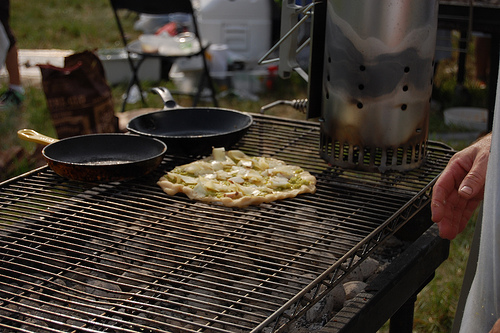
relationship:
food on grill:
[156, 144, 322, 208] [2, 92, 467, 324]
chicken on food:
[210, 143, 231, 159] [156, 144, 322, 208]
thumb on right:
[452, 153, 490, 202] [425, 127, 500, 246]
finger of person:
[426, 146, 469, 218] [428, 71, 499, 331]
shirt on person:
[459, 70, 495, 329] [428, 71, 499, 331]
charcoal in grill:
[14, 192, 388, 323] [2, 92, 467, 324]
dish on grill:
[16, 128, 168, 185] [2, 92, 467, 324]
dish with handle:
[16, 128, 168, 185] [13, 125, 60, 146]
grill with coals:
[2, 92, 467, 324] [8, 195, 400, 332]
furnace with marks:
[296, 2, 440, 171] [320, 94, 442, 158]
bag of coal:
[26, 46, 127, 140] [4, 211, 377, 331]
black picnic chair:
[166, 100, 181, 109] [104, 3, 232, 112]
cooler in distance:
[177, 2, 283, 73] [0, 4, 299, 98]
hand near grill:
[419, 128, 496, 244] [2, 92, 467, 324]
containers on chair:
[139, 32, 164, 52] [104, 3, 232, 112]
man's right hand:
[408, 126, 494, 235] [419, 128, 496, 244]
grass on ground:
[11, 2, 123, 52] [2, 92, 467, 324]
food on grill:
[163, 139, 322, 212] [2, 92, 467, 324]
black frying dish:
[166, 100, 181, 109] [16, 128, 168, 185]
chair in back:
[104, 3, 232, 112] [11, 2, 123, 57]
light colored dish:
[129, 80, 262, 150] [16, 128, 168, 185]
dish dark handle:
[16, 128, 168, 185] [13, 125, 60, 146]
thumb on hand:
[452, 153, 490, 202] [419, 128, 496, 244]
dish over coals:
[16, 115, 165, 186] [8, 195, 400, 332]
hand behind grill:
[419, 128, 496, 244] [2, 92, 467, 324]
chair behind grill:
[104, 3, 232, 112] [2, 92, 467, 324]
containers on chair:
[132, 23, 208, 62] [104, 3, 232, 112]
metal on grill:
[255, 90, 326, 123] [2, 92, 467, 324]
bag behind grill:
[26, 46, 127, 140] [2, 92, 467, 324]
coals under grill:
[8, 195, 400, 332] [2, 92, 467, 324]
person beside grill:
[428, 71, 499, 331] [2, 92, 467, 324]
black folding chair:
[166, 100, 181, 109] [104, 3, 232, 112]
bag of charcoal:
[26, 46, 127, 140] [14, 192, 388, 323]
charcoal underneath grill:
[14, 192, 388, 323] [2, 92, 467, 324]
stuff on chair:
[137, 28, 207, 66] [104, 3, 232, 112]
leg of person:
[3, 45, 30, 114] [428, 71, 499, 331]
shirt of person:
[459, 70, 495, 329] [428, 71, 499, 331]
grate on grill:
[17, 94, 447, 308] [2, 92, 467, 324]